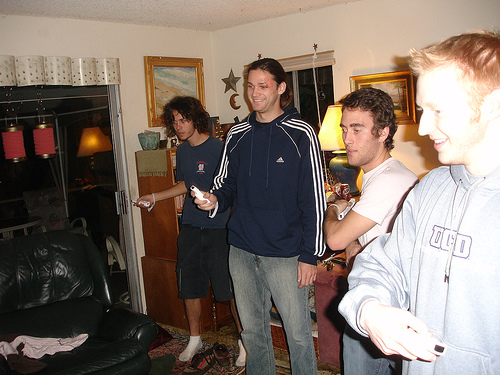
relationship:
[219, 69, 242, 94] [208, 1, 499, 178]
star on wall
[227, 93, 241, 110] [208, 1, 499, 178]
moon on wall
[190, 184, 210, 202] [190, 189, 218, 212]
controller in hand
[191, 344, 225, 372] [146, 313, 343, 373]
shoe on floor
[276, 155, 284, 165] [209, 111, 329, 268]
logo on hoodie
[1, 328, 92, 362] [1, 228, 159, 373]
cloth on chair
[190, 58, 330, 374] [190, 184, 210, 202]
man with controller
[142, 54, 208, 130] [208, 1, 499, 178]
frame on wall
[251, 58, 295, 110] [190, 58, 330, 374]
hair on man